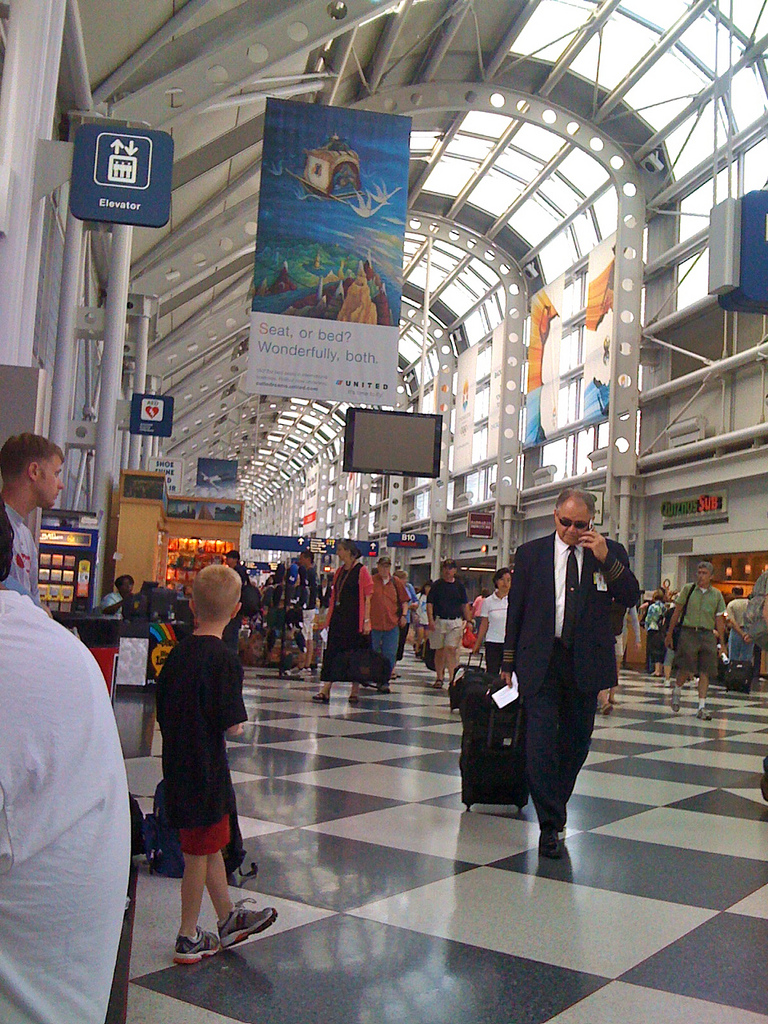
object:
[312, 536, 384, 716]
woman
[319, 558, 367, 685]
dress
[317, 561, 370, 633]
coat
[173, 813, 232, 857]
shorts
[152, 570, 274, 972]
boy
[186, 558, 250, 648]
head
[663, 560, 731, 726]
man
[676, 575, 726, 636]
shirt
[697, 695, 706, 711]
socks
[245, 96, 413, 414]
banner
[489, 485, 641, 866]
man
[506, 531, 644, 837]
suit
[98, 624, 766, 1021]
floor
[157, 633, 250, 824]
shirt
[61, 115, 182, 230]
sign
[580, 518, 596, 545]
cellphone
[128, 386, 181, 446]
sign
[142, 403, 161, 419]
heart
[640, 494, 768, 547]
wall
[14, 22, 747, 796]
building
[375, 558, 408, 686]
person